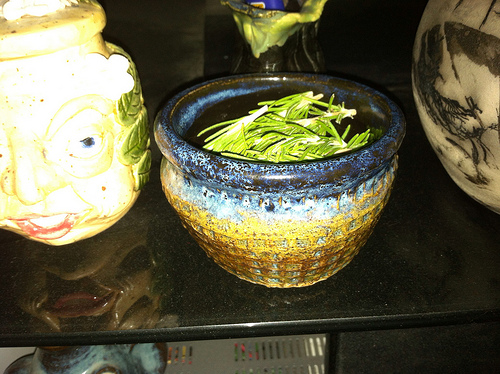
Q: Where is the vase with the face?
A: On the left.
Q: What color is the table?
A: Black.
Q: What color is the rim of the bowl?
A: Blue.